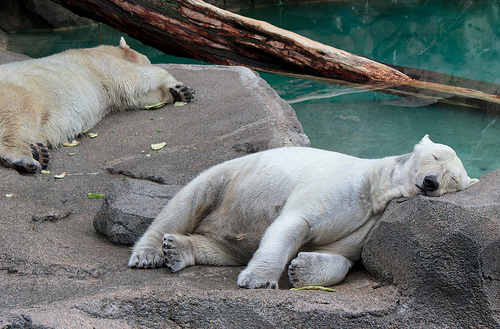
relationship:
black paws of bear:
[158, 74, 197, 107] [1, 35, 199, 175]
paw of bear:
[156, 227, 193, 282] [127, 130, 479, 295]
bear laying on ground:
[127, 130, 479, 295] [0, 65, 496, 325]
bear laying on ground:
[1, 35, 199, 175] [0, 65, 496, 325]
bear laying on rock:
[127, 130, 479, 295] [368, 192, 487, 269]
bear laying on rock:
[1, 35, 199, 175] [106, 105, 292, 154]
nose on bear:
[423, 176, 439, 191] [127, 132, 478, 288]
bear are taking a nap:
[127, 130, 479, 295] [0, 37, 489, 289]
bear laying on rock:
[1, 35, 199, 175] [4, 36, 359, 326]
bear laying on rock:
[127, 132, 478, 288] [359, 164, 497, 319]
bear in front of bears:
[127, 130, 479, 295] [2, 34, 196, 173]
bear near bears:
[127, 130, 479, 295] [2, 34, 196, 173]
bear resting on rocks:
[127, 132, 478, 288] [2, 64, 494, 326]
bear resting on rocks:
[1, 35, 199, 175] [2, 64, 494, 326]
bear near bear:
[127, 132, 478, 288] [1, 35, 199, 175]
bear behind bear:
[1, 35, 199, 175] [127, 132, 478, 288]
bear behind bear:
[1, 33, 203, 195] [123, 135, 475, 303]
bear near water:
[127, 132, 478, 288] [240, 0, 498, 157]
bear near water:
[1, 35, 199, 175] [240, 0, 498, 157]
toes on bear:
[126, 252, 139, 269] [127, 132, 478, 288]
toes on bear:
[156, 230, 188, 277] [127, 132, 478, 288]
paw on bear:
[282, 245, 369, 288] [154, 137, 459, 302]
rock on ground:
[99, 174, 188, 241] [0, 65, 496, 325]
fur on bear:
[237, 167, 312, 239] [127, 132, 478, 288]